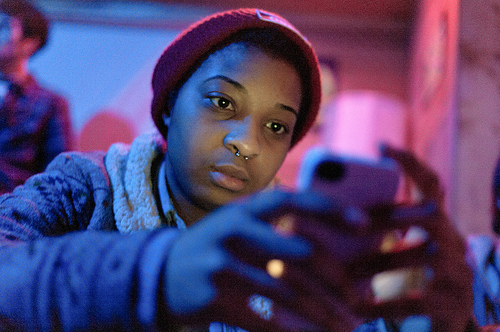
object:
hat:
[150, 8, 323, 152]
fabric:
[150, 7, 323, 149]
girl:
[1, 7, 476, 331]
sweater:
[1, 131, 386, 332]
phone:
[270, 147, 400, 331]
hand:
[165, 188, 362, 331]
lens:
[314, 159, 345, 182]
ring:
[235, 153, 248, 161]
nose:
[223, 116, 259, 158]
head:
[163, 27, 303, 212]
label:
[255, 10, 312, 48]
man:
[1, 0, 74, 194]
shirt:
[1, 72, 74, 195]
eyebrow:
[204, 74, 248, 93]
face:
[166, 44, 303, 208]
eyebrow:
[276, 104, 299, 119]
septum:
[240, 146, 246, 159]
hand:
[347, 141, 475, 332]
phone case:
[271, 147, 400, 330]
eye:
[263, 121, 290, 135]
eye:
[207, 92, 237, 113]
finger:
[250, 186, 371, 236]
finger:
[376, 143, 444, 204]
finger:
[218, 216, 374, 332]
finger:
[217, 263, 351, 332]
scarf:
[104, 132, 161, 235]